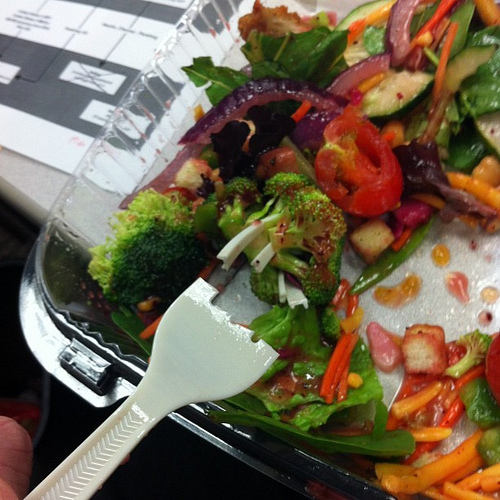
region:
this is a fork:
[29, 254, 331, 498]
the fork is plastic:
[27, 209, 324, 499]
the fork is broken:
[15, 185, 349, 498]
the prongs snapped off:
[216, 205, 326, 310]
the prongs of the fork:
[209, 208, 324, 315]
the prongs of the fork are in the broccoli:
[207, 177, 347, 325]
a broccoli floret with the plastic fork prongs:
[220, 176, 342, 323]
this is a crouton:
[395, 320, 448, 382]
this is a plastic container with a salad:
[13, 3, 491, 498]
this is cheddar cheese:
[376, 378, 494, 498]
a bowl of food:
[43, 140, 465, 420]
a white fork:
[47, 234, 347, 464]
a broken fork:
[161, 218, 311, 383]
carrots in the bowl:
[393, 383, 463, 473]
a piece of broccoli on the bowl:
[247, 184, 333, 261]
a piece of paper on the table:
[7, 15, 184, 173]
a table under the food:
[0, 129, 126, 238]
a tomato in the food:
[328, 114, 387, 187]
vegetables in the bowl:
[76, 38, 494, 368]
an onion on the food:
[206, 78, 345, 135]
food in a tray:
[70, 178, 198, 302]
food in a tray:
[212, 159, 328, 286]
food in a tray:
[294, 305, 360, 401]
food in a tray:
[350, 349, 441, 451]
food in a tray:
[380, 430, 484, 487]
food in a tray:
[283, 52, 360, 141]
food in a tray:
[221, 13, 319, 85]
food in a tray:
[397, 141, 498, 183]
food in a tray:
[380, 19, 460, 102]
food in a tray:
[446, 18, 498, 86]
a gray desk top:
[0, 0, 499, 472]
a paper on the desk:
[0, 0, 265, 195]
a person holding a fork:
[0, 415, 32, 498]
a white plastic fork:
[22, 276, 279, 498]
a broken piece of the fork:
[216, 213, 281, 271]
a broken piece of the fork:
[249, 241, 274, 273]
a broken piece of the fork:
[276, 270, 287, 304]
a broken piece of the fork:
[283, 280, 308, 308]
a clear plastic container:
[18, 0, 498, 499]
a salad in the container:
[85, 0, 498, 499]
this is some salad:
[215, 298, 352, 468]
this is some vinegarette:
[282, 205, 334, 286]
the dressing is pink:
[315, 203, 406, 408]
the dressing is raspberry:
[275, 296, 292, 369]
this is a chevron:
[72, 424, 137, 491]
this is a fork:
[95, 424, 185, 456]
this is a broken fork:
[205, 287, 317, 399]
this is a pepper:
[344, 182, 379, 265]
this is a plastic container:
[243, 448, 290, 475]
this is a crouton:
[347, 233, 468, 289]